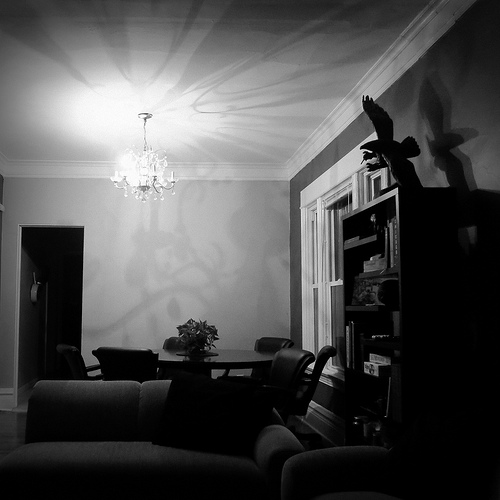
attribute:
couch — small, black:
[55, 371, 273, 489]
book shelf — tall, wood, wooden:
[330, 199, 435, 407]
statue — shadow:
[355, 93, 419, 186]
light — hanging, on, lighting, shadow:
[118, 123, 173, 202]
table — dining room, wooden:
[195, 351, 250, 372]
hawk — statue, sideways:
[358, 83, 403, 143]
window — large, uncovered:
[271, 177, 346, 335]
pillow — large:
[168, 379, 254, 456]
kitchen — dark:
[27, 326, 95, 376]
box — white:
[357, 360, 390, 379]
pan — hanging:
[25, 280, 43, 305]